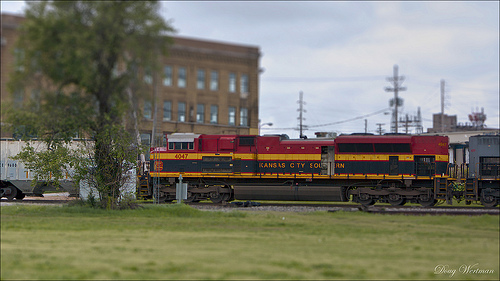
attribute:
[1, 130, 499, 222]
train — red, yellow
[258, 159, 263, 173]
letter — yellow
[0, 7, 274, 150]
building — multiple story, brick, tall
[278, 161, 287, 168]
letter — yellow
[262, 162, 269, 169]
letter — yellow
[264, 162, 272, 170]
letter — yellow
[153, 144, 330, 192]
letter — yellow